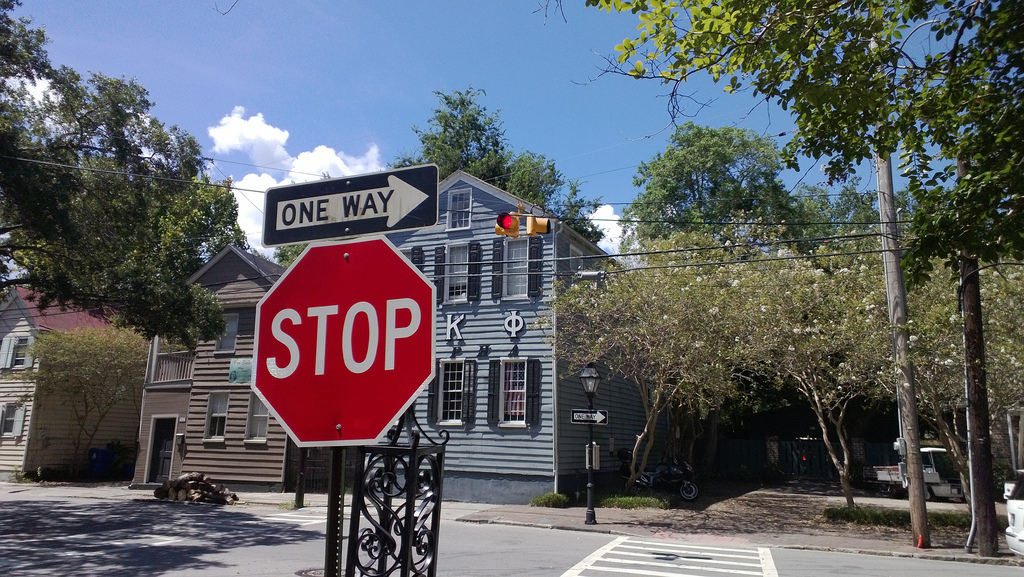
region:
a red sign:
[252, 248, 469, 452]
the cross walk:
[614, 542, 733, 575]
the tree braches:
[579, 261, 734, 376]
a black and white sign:
[263, 185, 450, 231]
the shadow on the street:
[118, 491, 208, 562]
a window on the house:
[493, 359, 538, 426]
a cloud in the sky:
[218, 115, 286, 167]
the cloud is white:
[211, 112, 291, 173]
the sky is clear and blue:
[355, 27, 447, 111]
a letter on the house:
[445, 311, 474, 349]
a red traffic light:
[490, 203, 525, 242]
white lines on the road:
[542, 523, 792, 572]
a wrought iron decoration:
[336, 409, 461, 572]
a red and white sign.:
[234, 230, 443, 458]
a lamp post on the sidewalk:
[563, 352, 627, 533]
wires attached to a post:
[560, 201, 881, 290]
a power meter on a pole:
[883, 429, 907, 465]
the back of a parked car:
[997, 489, 1021, 567]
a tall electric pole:
[864, 131, 941, 556]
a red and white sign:
[254, 236, 433, 468]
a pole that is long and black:
[302, 451, 354, 575]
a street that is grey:
[440, 527, 555, 572]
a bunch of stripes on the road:
[595, 523, 726, 575]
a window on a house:
[482, 358, 555, 436]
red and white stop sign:
[195, 235, 464, 454]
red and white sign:
[208, 221, 452, 478]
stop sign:
[231, 230, 443, 456]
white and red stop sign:
[253, 235, 446, 458]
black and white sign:
[255, 160, 455, 238]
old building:
[438, 185, 559, 502]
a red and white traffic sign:
[248, 232, 442, 448]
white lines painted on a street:
[566, 522, 789, 574]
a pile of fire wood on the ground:
[155, 466, 233, 504]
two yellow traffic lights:
[484, 196, 552, 242]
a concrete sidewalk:
[472, 488, 896, 572]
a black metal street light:
[564, 360, 615, 522]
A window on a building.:
[496, 349, 538, 438]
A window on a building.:
[499, 239, 531, 300]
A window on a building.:
[442, 239, 474, 309]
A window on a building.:
[438, 361, 470, 419]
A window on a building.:
[449, 188, 473, 230]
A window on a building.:
[247, 392, 268, 443]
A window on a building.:
[205, 387, 232, 435]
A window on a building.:
[220, 313, 236, 359]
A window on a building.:
[5, 403, 24, 436]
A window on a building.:
[13, 333, 27, 379]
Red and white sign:
[249, 247, 443, 456]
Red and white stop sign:
[258, 247, 433, 457]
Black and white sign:
[259, 168, 427, 244]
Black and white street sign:
[259, 161, 437, 244]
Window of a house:
[490, 353, 539, 427]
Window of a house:
[435, 357, 471, 421]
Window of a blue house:
[433, 358, 475, 426]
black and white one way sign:
[242, 161, 454, 245]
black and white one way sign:
[248, 146, 457, 251]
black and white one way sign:
[251, 146, 451, 251]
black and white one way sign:
[256, 146, 452, 260]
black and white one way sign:
[248, 141, 454, 262]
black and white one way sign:
[250, 141, 456, 269]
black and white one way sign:
[241, 152, 445, 263]